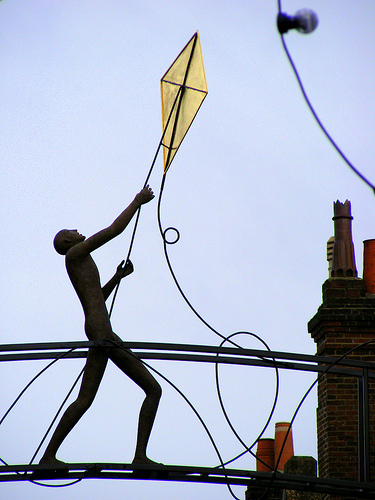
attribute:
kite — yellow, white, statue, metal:
[156, 30, 209, 177]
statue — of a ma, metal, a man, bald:
[34, 184, 170, 470]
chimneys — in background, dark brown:
[327, 194, 364, 280]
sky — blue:
[3, 1, 370, 500]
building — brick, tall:
[236, 200, 374, 499]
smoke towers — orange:
[271, 419, 296, 474]